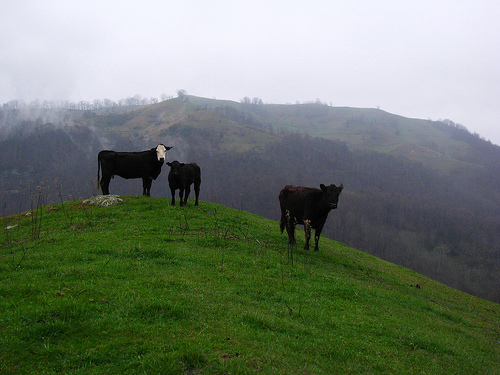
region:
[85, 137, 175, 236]
a cow is standing on a mountain top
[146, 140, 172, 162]
the cow has a white face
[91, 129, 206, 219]
the cows are standing together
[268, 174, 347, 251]
a cow is on the side of the hill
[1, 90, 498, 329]
mountains are behind the cows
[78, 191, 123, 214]
a rock is on top of the hill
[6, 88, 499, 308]
trees dot the hills behind the cows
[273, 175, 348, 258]
the cow is black with white areas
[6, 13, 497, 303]
the mountains are misty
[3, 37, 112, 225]
fog is coming of the trees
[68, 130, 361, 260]
three cows on a hill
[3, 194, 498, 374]
gree grassy hill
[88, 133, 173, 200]
black cow with a white face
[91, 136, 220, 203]
adult cow standing by a baby cow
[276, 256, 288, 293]
stick jutting out of the ground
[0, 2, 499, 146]
foggy gray sky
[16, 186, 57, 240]
group of sticks jutting out of the ground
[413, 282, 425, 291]
clump of dirt on the ground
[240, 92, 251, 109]
tree on the top of the mountain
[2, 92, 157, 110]
row of trees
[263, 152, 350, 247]
the cow is black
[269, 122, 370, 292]
the cow is black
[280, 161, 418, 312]
the cow is black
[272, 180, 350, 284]
the cow is black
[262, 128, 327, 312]
the cow is black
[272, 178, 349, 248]
this is a cow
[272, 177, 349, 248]
the cow is standing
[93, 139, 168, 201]
the cow is big in size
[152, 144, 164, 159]
the face is white in color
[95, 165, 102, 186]
the tail is long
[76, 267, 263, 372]
the grass is green in color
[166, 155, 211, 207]
this is a calf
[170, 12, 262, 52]
the sky is white in color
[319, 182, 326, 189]
this is the ear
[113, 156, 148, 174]
the cow is black in color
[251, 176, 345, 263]
black cow standing on hill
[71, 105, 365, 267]
three cows standing on hill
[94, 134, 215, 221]
two cows standing on hill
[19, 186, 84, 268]
plants on top of grass on hill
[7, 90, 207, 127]
trees out on the horizon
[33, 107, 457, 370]
large green hill with grass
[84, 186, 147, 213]
rock on top of hill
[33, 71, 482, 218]
large hill in the background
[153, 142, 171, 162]
white face of a cow looking forward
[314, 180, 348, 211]
black face of a cow